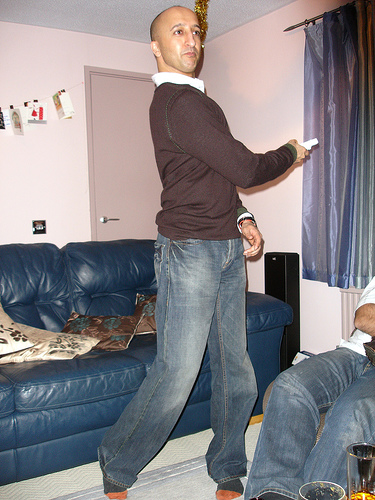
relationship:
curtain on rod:
[301, 5, 375, 289] [283, 2, 373, 32]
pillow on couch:
[61, 310, 144, 352] [0, 239, 294, 489]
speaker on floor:
[264, 252, 301, 373] [0, 368, 375, 500]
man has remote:
[96, 5, 313, 500] [298, 138, 318, 153]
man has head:
[96, 5, 313, 500] [150, 7, 203, 80]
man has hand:
[96, 5, 313, 500] [287, 139, 310, 164]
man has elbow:
[244, 274, 375, 500] [353, 304, 375, 339]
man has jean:
[96, 5, 313, 500] [96, 234, 261, 489]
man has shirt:
[96, 5, 313, 500] [150, 82, 296, 242]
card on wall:
[51, 88, 76, 121] [1, 1, 375, 359]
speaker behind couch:
[264, 252, 301, 373] [0, 239, 294, 489]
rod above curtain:
[283, 2, 373, 32] [301, 5, 375, 289]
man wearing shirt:
[96, 5, 313, 500] [150, 82, 296, 242]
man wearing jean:
[96, 5, 313, 500] [96, 234, 261, 489]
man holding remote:
[96, 5, 313, 500] [298, 138, 318, 153]